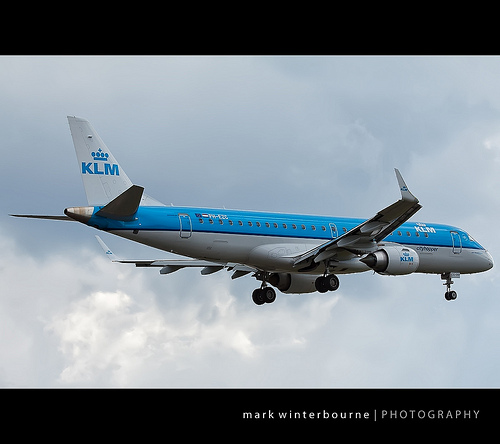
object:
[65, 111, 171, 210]
tail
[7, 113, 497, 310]
plane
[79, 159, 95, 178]
klm letters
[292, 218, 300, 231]
windows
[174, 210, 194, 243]
door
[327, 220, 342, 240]
door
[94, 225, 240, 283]
wing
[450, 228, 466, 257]
door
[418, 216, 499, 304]
front of plane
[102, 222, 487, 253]
stripe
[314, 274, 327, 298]
landing gear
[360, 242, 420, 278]
engine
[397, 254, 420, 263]
klm logo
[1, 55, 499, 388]
sky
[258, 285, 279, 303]
back landing gear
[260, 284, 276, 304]
wheels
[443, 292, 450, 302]
landing gear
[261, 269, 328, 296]
engine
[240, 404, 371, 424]
watermark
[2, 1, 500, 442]
photo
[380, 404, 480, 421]
photography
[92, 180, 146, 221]
back wing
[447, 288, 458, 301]
front wheels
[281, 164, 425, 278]
jet flaps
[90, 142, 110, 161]
logo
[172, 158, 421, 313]
middle of plane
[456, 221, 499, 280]
nose of plane